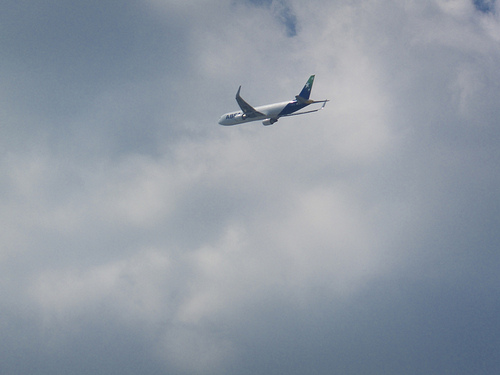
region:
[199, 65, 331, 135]
white plane in sky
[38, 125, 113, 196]
white clouds in blue sky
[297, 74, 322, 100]
blue tail of plane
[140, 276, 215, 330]
white clouds in blue sky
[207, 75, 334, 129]
white plane in blue sky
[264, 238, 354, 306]
white clouds in gray sky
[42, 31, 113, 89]
white clouds in gray sky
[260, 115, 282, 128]
white engine of plane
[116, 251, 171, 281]
white clouds in gray sky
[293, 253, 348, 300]
white clouds in gray sky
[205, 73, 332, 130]
plane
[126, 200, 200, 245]
white clouds in gray sky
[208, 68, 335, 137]
white plane in cloudy sky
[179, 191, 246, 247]
white clouds in blue sky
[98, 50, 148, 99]
white clouds in blue sky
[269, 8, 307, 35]
white clouds in blue sky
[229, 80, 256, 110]
wing of plane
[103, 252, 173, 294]
white clouds in blue sky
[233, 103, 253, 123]
engine of plane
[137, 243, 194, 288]
white clouds in blue sky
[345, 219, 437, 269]
white clouds in blue sky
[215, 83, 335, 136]
plane in the sky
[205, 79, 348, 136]
a blue and white plane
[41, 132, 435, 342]
sky filled with clouds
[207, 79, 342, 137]
a plane in midair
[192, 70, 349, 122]
a plane in midflight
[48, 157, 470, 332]
white and grey clouds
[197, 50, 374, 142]
plane flyng in overcast sky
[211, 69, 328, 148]
multicolor plane flying in the air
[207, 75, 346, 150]
a plane in the air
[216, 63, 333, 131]
an airplane in the sky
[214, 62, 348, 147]
a passenger plane in the sky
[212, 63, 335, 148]
a passenger airplane in the sky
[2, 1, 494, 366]
a sky with clouds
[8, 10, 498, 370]
a sky with white clouds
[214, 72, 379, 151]
a passenger airplane flying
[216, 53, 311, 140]
an airplane with blue tail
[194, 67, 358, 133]
a white airplane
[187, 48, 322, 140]
a white plane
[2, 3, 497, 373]
cloud cover in sky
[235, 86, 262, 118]
wing with upturned tip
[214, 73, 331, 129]
white airplane flying in sky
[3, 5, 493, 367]
cloudy sky with white airplane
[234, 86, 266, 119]
left wing of white airplane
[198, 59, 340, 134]
white plane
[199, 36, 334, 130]
plane in sky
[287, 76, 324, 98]
blue tail of white plane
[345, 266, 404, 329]
white clouds in blue sky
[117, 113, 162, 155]
white clouds in blue sky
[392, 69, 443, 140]
white clouds in blue sky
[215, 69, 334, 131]
an airplane in the sky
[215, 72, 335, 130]
an airplane with a bent wing tip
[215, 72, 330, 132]
an airplane with letters on the nose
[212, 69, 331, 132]
an airplane with a dark colored tail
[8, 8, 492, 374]
a cloudy sky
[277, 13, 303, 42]
blue sky peeking thru the clouds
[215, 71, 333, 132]
a blue and white airplane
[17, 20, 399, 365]
white clouds in the sky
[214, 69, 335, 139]
an airplane in the clouds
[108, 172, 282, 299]
clouds in the sky